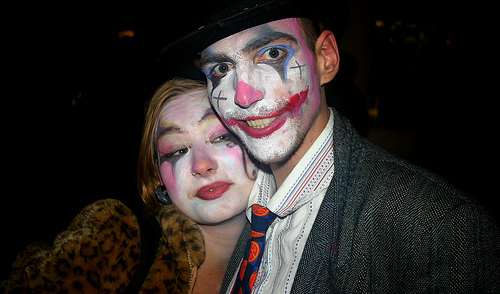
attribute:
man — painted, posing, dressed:
[196, 17, 499, 289]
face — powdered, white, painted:
[195, 19, 322, 164]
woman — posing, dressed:
[1, 78, 260, 292]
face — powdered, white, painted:
[156, 93, 261, 225]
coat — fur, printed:
[2, 199, 206, 294]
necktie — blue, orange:
[231, 205, 278, 292]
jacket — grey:
[290, 107, 500, 292]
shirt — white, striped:
[225, 106, 334, 293]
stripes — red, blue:
[276, 131, 338, 216]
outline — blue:
[255, 45, 295, 82]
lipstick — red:
[221, 89, 310, 138]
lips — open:
[236, 112, 289, 136]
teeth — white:
[247, 116, 278, 128]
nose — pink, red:
[234, 82, 263, 107]